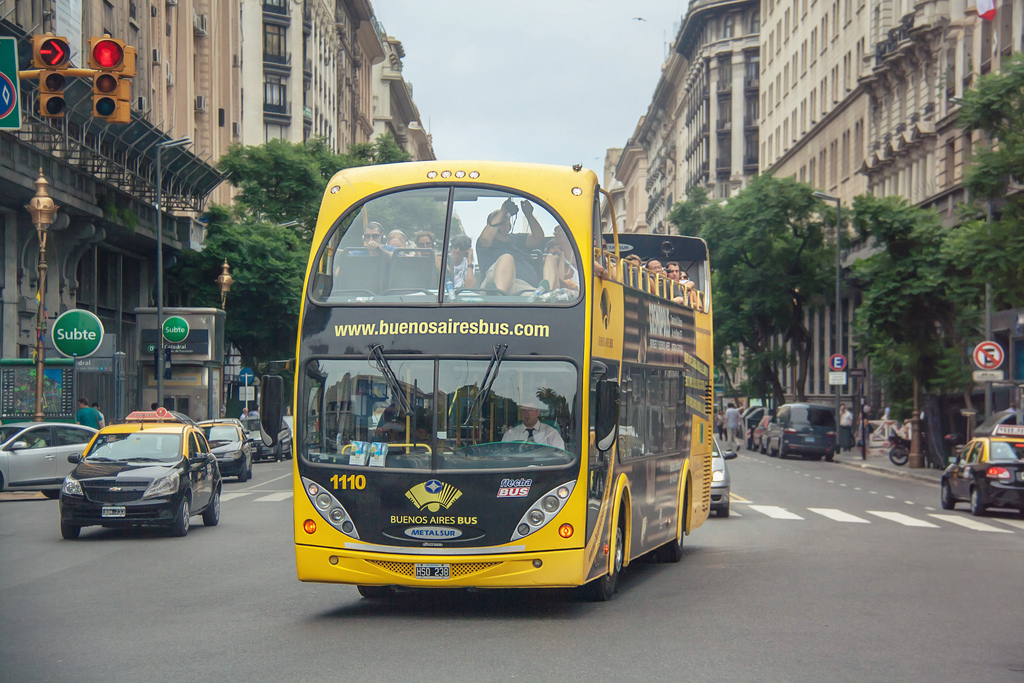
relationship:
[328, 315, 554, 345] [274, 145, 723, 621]
brand name on bus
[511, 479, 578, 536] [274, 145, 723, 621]
headlight on bus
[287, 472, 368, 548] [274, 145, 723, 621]
headlight on bus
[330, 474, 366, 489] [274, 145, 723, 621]
number on bus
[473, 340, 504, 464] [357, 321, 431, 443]
wiper on windshield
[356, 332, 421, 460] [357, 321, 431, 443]
wiper on windshield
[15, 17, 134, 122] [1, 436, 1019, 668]
traffic lights above street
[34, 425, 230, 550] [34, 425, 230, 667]
car in street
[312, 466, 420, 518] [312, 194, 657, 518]
number on bus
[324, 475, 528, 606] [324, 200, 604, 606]
plate on bus